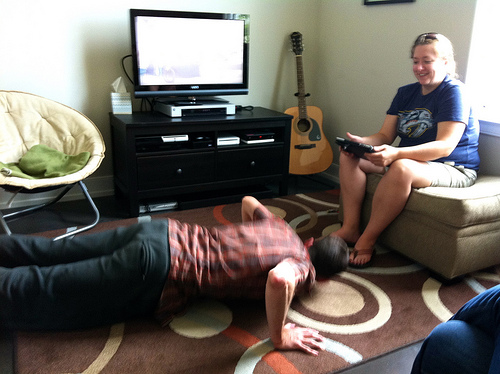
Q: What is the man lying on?
A: A brown patterned rug.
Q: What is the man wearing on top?
A: A red plaid shirt.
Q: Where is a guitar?
A: In a corner.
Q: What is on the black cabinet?
A: A flat screen television.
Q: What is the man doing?
A: Pushups.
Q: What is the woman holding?
A: A tablet.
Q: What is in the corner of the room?
A: A guitar.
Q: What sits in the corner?
A: A guitar.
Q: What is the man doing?
A: Push ups.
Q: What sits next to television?
A: A box of tissues?.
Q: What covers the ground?
A: A brown rug with circular patterns.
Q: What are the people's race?
A: Caucasian.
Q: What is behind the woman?
A: A window.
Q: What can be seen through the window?
A: Day light.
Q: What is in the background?
A: An entertainment unit.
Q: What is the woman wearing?
A: A blue and white shirt.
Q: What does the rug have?
A: Circles.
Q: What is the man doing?
A: Push ups.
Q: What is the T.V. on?
A: A black stand.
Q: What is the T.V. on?
A: A stand.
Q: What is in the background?
A: A round chair.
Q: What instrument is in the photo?
A: Guitar.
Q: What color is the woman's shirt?
A: Blue.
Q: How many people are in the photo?
A: Two.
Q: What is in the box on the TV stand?
A: Tissues.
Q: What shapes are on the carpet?
A: Circles.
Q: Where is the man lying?
A: On the floor.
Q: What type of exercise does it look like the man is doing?
A: Push up.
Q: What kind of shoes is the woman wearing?
A: Flip flops.